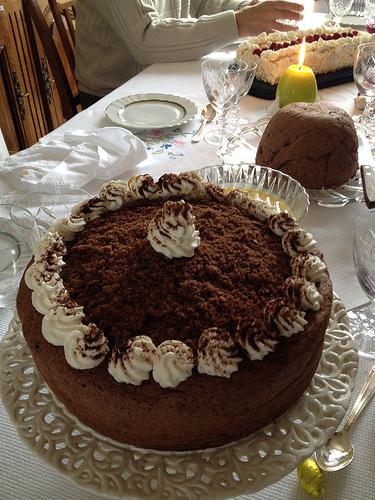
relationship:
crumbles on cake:
[58, 194, 294, 345] [6, 167, 347, 461]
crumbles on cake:
[63, 198, 289, 342] [6, 167, 347, 461]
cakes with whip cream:
[16, 171, 333, 450] [145, 198, 201, 259]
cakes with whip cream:
[16, 171, 333, 450] [25, 172, 326, 388]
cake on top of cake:
[227, 22, 373, 102] [232, 22, 373, 86]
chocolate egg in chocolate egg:
[302, 457, 321, 495] [296, 458, 321, 500]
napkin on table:
[8, 124, 148, 200] [0, 11, 373, 499]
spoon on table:
[314, 366, 375, 474] [0, 11, 373, 499]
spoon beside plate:
[190, 102, 215, 142] [105, 86, 199, 132]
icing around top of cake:
[21, 173, 328, 384] [6, 167, 347, 461]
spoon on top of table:
[313, 337, 358, 472] [0, 11, 373, 499]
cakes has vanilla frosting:
[16, 171, 333, 450] [293, 273, 318, 307]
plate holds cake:
[3, 169, 365, 495] [23, 172, 334, 453]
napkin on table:
[0, 127, 148, 197] [0, 11, 373, 499]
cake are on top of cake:
[227, 22, 373, 102] [233, 13, 373, 114]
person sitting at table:
[71, 0, 307, 111] [0, 11, 373, 499]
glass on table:
[201, 58, 258, 147] [0, 11, 373, 499]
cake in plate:
[6, 167, 347, 461] [4, 293, 359, 463]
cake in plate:
[232, 22, 373, 86] [105, 91, 199, 131]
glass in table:
[192, 41, 275, 124] [81, 71, 242, 172]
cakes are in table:
[9, 15, 373, 462] [0, 11, 373, 499]